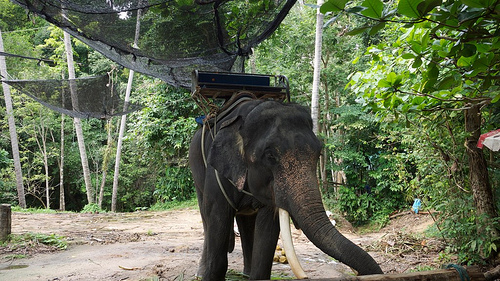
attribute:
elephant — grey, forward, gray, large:
[187, 96, 385, 279]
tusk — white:
[277, 205, 311, 279]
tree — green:
[318, 5, 498, 253]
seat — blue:
[191, 67, 292, 119]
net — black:
[10, 0, 301, 93]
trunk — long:
[282, 174, 386, 275]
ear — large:
[204, 114, 249, 188]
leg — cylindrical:
[193, 201, 234, 280]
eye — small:
[264, 152, 280, 166]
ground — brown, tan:
[3, 205, 460, 278]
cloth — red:
[474, 127, 499, 152]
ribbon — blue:
[410, 197, 422, 214]